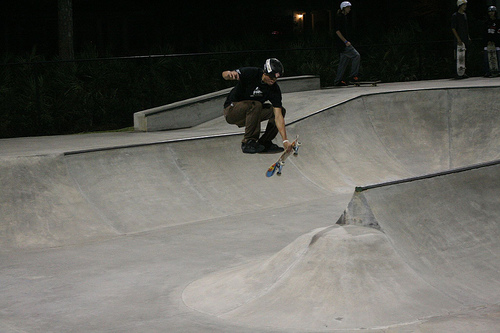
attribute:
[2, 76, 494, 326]
ramp — smaller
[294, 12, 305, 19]
light — orange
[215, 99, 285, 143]
pants — brown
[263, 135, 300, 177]
board — blue , brown 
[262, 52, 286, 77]
helmet — gray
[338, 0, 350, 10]
helmet — white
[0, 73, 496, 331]
skate park — grey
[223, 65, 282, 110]
shirt —  black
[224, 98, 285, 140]
pants —  gray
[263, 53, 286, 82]
helmet — White , black 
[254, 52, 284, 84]
helmet — black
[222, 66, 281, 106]
shirt — black, white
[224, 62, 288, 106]
tshirt — black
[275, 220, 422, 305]
ramp —  lighter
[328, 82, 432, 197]
ramp — grey 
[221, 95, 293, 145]
pants — brown 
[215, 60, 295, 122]
shirt — black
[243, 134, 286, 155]
shoes — black 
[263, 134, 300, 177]
skateboard —  white